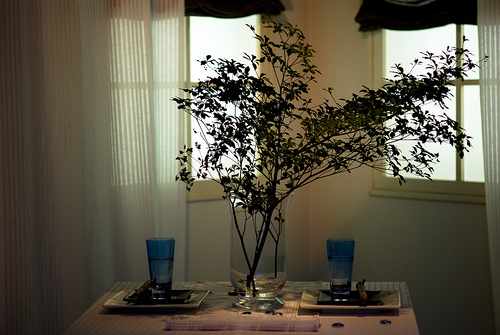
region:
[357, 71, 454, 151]
small tree in shadow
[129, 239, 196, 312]
food plate settings blue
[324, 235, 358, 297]
blue cup to fade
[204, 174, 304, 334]
water in vase with stems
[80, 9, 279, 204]
window with light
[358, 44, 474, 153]
backlit tree in shadow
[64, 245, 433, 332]
small table for two people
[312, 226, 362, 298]
large blue cup on the right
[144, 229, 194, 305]
large blue cup on the left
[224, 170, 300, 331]
large clear glass vase on table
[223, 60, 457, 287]
tree branches in vase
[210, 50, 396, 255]
tree branches with green leaves on table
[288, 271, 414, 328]
two plates on table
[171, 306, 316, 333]
place mat on table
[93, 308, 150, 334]
light green striped table cloth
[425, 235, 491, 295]
white area of wall in room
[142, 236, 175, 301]
A blue and clear glass to the left of another.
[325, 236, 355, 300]
A blue and clear glass on the table to the right of another.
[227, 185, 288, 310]
A very large clear glass vase holding a plant.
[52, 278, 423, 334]
A small table with two glasses and a plant in a vase on top.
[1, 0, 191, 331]
A long white see through curtain to the left of a plant.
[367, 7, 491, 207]
A white window frame to the right of a plant.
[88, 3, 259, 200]
A window with light coming through to the left of a plant.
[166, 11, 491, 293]
A green and brown plant in a large vase.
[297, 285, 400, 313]
A white square plate to the right of a plant on the table.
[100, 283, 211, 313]
A white square plate to the left of another.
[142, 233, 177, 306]
The cup is blue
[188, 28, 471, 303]
The plant is in a vase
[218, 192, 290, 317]
The vase is clear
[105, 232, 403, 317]
There are two plates on the table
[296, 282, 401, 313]
The plate is square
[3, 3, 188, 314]
The curtain is white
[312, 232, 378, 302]
The cup is on a black plate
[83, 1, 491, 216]
There are two windows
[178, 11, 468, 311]
The plant has many leaves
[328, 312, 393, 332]
There are two leaves on the table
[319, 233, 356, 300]
blue glass on the plate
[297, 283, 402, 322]
plates sitting on the table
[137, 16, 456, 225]
small thin tree limbs in the vase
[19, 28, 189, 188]
white sheer curtain in the window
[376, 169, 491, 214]
white wooden window sill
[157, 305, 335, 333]
cloth napkins on the table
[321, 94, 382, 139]
small green leaves on the limbs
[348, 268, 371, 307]
chop sticks on the plate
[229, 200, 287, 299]
water and stems in the vase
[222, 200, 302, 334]
clear vase on the table